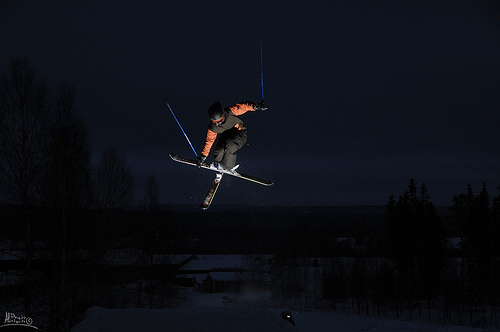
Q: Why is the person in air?
A: Jumping.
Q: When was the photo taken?
A: Night.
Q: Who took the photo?
A: Fan.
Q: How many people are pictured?
A: One.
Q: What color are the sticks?
A: Blue.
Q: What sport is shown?
A: Skiing.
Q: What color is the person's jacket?
A: Orange.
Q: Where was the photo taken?
A: Slopes.